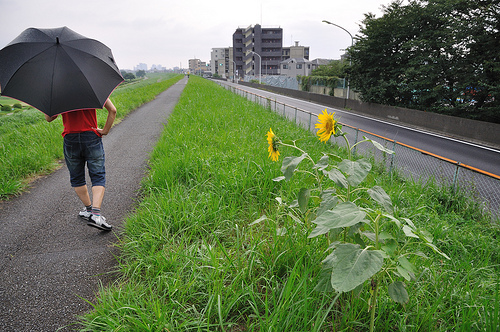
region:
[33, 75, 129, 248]
man walking with umbrella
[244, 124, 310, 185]
sunflower is yellow and vibrant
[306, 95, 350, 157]
sunflower is yellow and vibrant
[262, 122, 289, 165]
sunflower is yellow and vibrant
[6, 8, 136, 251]
a person is walking with an umbrella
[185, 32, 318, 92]
a group of building on the right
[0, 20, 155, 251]
man is walking down a paved path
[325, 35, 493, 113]
leafy tree top on the side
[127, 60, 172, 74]
a city's skyline far off on the horizon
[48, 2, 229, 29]
the sky is overcast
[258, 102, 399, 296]
a plant with yellow flowers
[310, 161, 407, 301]
green leaves of a plant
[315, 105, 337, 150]
yellow petals of a flower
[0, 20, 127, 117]
a black umbrella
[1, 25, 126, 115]
Black umbrella open above a person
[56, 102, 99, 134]
Red shirt on person with umbrella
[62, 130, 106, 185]
Knee length jean on person with umbrella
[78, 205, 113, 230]
White and black shoes on person with umbrella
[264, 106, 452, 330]
Sunflower plant on side of road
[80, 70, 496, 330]
Green grass on side of road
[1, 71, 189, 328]
Paved walking path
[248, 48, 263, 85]
Street light along road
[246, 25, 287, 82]
Six story building in the distance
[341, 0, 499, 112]
Green trees along a road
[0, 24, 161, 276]
Man walking down asphalt path.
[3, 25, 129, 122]
A black open umbrella.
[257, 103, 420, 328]
Sunflowers growing on side of asphalt path.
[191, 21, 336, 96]
Buildings in distance next to road.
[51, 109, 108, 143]
Man dressed in red t-shirt.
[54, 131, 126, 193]
Man dressed in blue jeans.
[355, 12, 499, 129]
Tree growing next to road.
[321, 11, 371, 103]
Lamp post hanging over road.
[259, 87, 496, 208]
Chain link fence along asphalt path.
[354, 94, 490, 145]
Concrete guard wall along road.